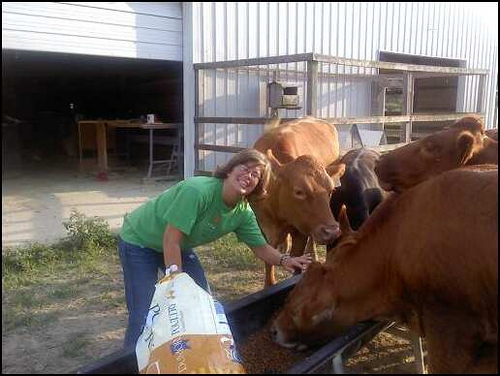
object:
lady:
[118, 150, 311, 347]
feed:
[265, 306, 302, 352]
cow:
[271, 163, 499, 371]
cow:
[326, 145, 390, 244]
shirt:
[118, 175, 266, 252]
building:
[3, 3, 499, 181]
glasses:
[237, 162, 260, 178]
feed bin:
[64, 272, 391, 374]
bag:
[135, 271, 245, 374]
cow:
[245, 116, 345, 289]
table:
[80, 121, 182, 183]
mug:
[147, 114, 155, 124]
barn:
[3, 3, 498, 180]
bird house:
[191, 52, 488, 175]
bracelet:
[278, 255, 288, 266]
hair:
[214, 150, 271, 204]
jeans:
[119, 235, 213, 351]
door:
[0, 0, 183, 62]